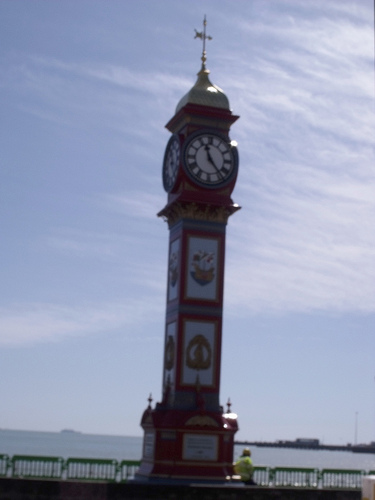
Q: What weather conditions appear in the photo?
A: It is sunny.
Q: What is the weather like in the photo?
A: It is sunny.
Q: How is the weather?
A: It is sunny.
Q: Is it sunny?
A: Yes, it is sunny.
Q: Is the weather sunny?
A: Yes, it is sunny.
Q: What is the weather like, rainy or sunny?
A: It is sunny.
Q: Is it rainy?
A: No, it is sunny.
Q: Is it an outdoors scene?
A: Yes, it is outdoors.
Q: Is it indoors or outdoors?
A: It is outdoors.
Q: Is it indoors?
A: No, it is outdoors.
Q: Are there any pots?
A: No, there are no pots.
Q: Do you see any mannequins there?
A: No, there are no mannequins.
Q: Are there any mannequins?
A: No, there are no mannequins.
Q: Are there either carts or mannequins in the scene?
A: No, there are no mannequins or carts.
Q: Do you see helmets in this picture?
A: No, there are no helmets.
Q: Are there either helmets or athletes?
A: No, there are no helmets or athletes.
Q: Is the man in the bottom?
A: Yes, the man is in the bottom of the image.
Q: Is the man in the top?
A: No, the man is in the bottom of the image.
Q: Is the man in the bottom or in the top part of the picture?
A: The man is in the bottom of the image.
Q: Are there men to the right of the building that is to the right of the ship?
A: Yes, there is a man to the right of the tower.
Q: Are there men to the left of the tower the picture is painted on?
A: No, the man is to the right of the tower.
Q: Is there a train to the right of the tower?
A: No, there is a man to the right of the tower.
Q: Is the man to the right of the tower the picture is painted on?
A: Yes, the man is to the right of the tower.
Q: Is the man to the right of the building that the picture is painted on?
A: Yes, the man is to the right of the tower.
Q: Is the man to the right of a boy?
A: No, the man is to the right of the tower.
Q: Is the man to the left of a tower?
A: No, the man is to the right of a tower.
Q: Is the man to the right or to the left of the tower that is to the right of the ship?
A: The man is to the right of the tower.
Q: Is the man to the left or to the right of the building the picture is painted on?
A: The man is to the right of the tower.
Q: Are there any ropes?
A: No, there are no ropes.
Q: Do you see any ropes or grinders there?
A: No, there are no ropes or grinders.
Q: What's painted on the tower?
A: The picture is painted on the tower.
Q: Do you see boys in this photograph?
A: No, there are no boys.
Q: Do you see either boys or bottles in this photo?
A: No, there are no boys or bottles.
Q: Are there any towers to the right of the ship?
A: Yes, there is a tower to the right of the ship.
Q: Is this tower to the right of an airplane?
A: No, the tower is to the right of a ship.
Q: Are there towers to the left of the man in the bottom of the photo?
A: Yes, there is a tower to the left of the man.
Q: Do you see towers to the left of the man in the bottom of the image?
A: Yes, there is a tower to the left of the man.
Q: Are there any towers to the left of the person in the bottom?
A: Yes, there is a tower to the left of the man.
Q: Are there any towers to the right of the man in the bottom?
A: No, the tower is to the left of the man.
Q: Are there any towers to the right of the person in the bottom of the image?
A: No, the tower is to the left of the man.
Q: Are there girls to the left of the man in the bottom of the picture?
A: No, there is a tower to the left of the man.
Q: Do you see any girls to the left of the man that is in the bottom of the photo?
A: No, there is a tower to the left of the man.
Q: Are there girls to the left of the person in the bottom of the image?
A: No, there is a tower to the left of the man.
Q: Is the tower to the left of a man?
A: Yes, the tower is to the left of a man.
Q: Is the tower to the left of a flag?
A: No, the tower is to the left of a man.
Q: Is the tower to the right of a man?
A: No, the tower is to the left of a man.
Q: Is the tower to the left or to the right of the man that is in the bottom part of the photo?
A: The tower is to the left of the man.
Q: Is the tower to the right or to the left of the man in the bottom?
A: The tower is to the left of the man.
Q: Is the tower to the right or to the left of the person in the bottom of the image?
A: The tower is to the left of the man.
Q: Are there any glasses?
A: No, there are no glasses.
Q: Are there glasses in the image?
A: No, there are no glasses.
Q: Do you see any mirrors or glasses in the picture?
A: No, there are no glasses or mirrors.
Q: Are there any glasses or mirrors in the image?
A: No, there are no glasses or mirrors.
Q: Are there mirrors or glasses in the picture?
A: No, there are no glasses or mirrors.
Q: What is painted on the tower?
A: The picture is painted on the tower.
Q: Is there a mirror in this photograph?
A: No, there are no mirrors.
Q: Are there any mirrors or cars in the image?
A: No, there are no mirrors or cars.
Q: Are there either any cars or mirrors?
A: No, there are no mirrors or cars.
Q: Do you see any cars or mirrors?
A: No, there are no mirrors or cars.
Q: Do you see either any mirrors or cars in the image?
A: No, there are no mirrors or cars.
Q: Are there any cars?
A: No, there are no cars.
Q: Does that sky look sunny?
A: Yes, the sky is sunny.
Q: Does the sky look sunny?
A: Yes, the sky is sunny.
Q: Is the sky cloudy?
A: No, the sky is sunny.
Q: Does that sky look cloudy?
A: No, the sky is sunny.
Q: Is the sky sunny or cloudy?
A: The sky is sunny.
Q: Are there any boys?
A: No, there are no boys.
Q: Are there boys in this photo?
A: No, there are no boys.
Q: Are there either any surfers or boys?
A: No, there are no boys or surfers.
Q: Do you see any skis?
A: No, there are no skis.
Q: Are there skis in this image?
A: No, there are no skis.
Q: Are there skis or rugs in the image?
A: No, there are no skis or rugs.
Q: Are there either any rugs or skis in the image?
A: No, there are no skis or rugs.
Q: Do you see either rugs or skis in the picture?
A: No, there are no skis or rugs.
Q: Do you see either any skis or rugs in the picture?
A: No, there are no skis or rugs.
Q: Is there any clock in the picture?
A: Yes, there is a clock.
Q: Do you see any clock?
A: Yes, there is a clock.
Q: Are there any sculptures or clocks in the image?
A: Yes, there is a clock.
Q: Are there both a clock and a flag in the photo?
A: No, there is a clock but no flags.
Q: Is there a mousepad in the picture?
A: No, there are no mouse pads.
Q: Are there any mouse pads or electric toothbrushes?
A: No, there are no mouse pads or electric toothbrushes.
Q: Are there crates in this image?
A: No, there are no crates.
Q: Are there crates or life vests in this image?
A: No, there are no crates or life vests.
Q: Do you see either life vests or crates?
A: No, there are no crates or life vests.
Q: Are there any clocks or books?
A: Yes, there is a clock.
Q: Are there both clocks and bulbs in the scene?
A: No, there is a clock but no light bulbs.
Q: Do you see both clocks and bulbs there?
A: No, there is a clock but no light bulbs.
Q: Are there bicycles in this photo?
A: No, there are no bicycles.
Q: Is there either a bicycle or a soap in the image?
A: No, there are no bicycles or soaps.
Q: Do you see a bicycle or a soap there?
A: No, there are no bicycles or soaps.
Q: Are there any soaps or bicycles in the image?
A: No, there are no bicycles or soaps.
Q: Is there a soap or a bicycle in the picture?
A: No, there are no bicycles or soaps.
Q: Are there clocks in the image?
A: Yes, there is a clock.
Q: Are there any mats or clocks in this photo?
A: Yes, there is a clock.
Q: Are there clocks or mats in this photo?
A: Yes, there is a clock.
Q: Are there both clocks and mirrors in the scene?
A: No, there is a clock but no mirrors.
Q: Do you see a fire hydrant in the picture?
A: No, there are no fire hydrants.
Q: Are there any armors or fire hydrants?
A: No, there are no fire hydrants or armors.